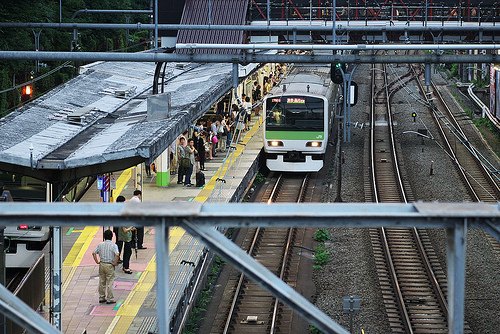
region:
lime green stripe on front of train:
[274, 126, 314, 143]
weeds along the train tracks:
[306, 225, 337, 267]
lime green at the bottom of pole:
[147, 163, 177, 188]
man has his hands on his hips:
[95, 237, 120, 271]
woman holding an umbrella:
[137, 231, 144, 261]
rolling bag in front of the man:
[187, 163, 210, 189]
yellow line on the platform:
[211, 157, 232, 199]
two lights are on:
[263, 142, 316, 153]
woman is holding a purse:
[211, 129, 220, 140]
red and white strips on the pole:
[98, 173, 123, 194]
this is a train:
[261, 82, 335, 167]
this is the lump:
[307, 138, 323, 153]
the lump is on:
[307, 134, 319, 151]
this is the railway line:
[250, 238, 292, 255]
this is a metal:
[383, 258, 403, 290]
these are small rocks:
[336, 245, 356, 275]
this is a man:
[96, 233, 121, 286]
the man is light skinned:
[111, 249, 121, 261]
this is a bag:
[196, 165, 207, 182]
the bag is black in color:
[196, 170, 207, 187]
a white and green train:
[263, 70, 329, 175]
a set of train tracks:
[217, 163, 307, 331]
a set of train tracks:
[365, 57, 455, 329]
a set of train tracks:
[403, 63, 494, 219]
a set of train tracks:
[385, 68, 411, 98]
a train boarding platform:
[30, 59, 287, 326]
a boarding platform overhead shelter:
[0, 40, 272, 182]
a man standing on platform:
[93, 229, 120, 301]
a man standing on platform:
[128, 190, 146, 248]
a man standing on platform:
[172, 135, 192, 184]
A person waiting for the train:
[93, 231, 122, 303]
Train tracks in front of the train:
[233, 285, 278, 330]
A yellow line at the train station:
[132, 275, 151, 325]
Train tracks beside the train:
[369, 93, 402, 195]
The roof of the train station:
[7, 55, 259, 165]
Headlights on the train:
[268, 136, 323, 148]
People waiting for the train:
[176, 117, 230, 185]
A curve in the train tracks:
[368, 70, 412, 103]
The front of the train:
[266, 95, 323, 170]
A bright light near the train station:
[21, 83, 34, 94]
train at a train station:
[253, 40, 343, 179]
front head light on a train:
[301, 136, 326, 151]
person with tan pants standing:
[88, 227, 128, 309]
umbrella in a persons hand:
[128, 225, 143, 261]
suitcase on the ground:
[192, 159, 210, 190]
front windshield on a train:
[261, 90, 327, 134]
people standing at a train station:
[172, 132, 210, 191]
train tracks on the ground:
[357, 57, 412, 207]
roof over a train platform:
[0, 61, 239, 189]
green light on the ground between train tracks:
[406, 107, 422, 129]